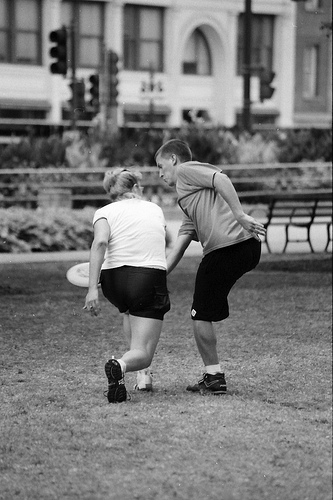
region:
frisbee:
[49, 211, 145, 318]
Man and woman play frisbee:
[82, 133, 277, 393]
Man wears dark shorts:
[151, 136, 288, 331]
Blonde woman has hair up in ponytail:
[86, 151, 162, 227]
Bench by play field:
[226, 144, 331, 302]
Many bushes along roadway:
[48, 106, 323, 245]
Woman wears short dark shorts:
[75, 147, 174, 409]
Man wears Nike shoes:
[178, 308, 235, 409]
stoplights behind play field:
[31, 15, 181, 195]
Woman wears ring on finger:
[61, 244, 221, 389]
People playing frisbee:
[68, 133, 273, 411]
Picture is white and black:
[1, 3, 331, 498]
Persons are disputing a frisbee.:
[59, 137, 273, 420]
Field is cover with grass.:
[6, 259, 330, 496]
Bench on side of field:
[236, 181, 330, 252]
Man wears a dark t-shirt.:
[149, 131, 286, 401]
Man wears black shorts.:
[152, 133, 277, 413]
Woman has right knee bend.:
[77, 156, 177, 410]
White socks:
[196, 360, 231, 381]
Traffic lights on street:
[37, 19, 290, 125]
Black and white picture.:
[20, 17, 313, 470]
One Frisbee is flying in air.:
[64, 256, 109, 297]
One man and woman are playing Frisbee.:
[71, 155, 247, 394]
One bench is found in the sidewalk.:
[250, 184, 331, 256]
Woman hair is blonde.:
[105, 171, 135, 190]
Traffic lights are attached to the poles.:
[43, 28, 274, 122]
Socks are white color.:
[85, 344, 231, 387]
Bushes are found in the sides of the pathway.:
[6, 203, 86, 236]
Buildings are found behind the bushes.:
[12, 14, 299, 89]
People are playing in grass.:
[29, 246, 265, 408]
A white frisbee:
[61, 259, 102, 289]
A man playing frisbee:
[156, 138, 270, 398]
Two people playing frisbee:
[68, 143, 265, 399]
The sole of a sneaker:
[97, 357, 130, 402]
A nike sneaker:
[180, 369, 231, 396]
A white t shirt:
[92, 199, 173, 269]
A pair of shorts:
[189, 235, 261, 322]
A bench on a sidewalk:
[248, 187, 331, 255]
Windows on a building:
[1, 2, 170, 74]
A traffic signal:
[41, 23, 70, 77]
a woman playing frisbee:
[64, 162, 181, 405]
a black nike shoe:
[179, 370, 233, 400]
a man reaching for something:
[147, 131, 275, 400]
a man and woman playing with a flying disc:
[50, 129, 275, 403]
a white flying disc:
[58, 257, 105, 290]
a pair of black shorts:
[186, 231, 264, 328]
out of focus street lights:
[41, 17, 135, 119]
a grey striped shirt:
[166, 157, 266, 255]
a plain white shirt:
[82, 195, 174, 279]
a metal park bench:
[239, 186, 331, 262]